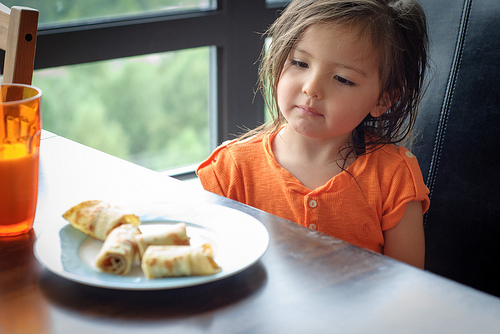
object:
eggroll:
[61, 199, 139, 241]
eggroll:
[136, 221, 189, 246]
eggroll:
[93, 223, 137, 275]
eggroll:
[140, 242, 223, 277]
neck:
[266, 128, 361, 173]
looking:
[272, 47, 378, 102]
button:
[308, 200, 319, 208]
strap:
[395, 144, 431, 199]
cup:
[0, 82, 42, 248]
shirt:
[194, 122, 430, 253]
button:
[404, 150, 414, 159]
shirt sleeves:
[371, 138, 432, 231]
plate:
[30, 196, 270, 290]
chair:
[0, 4, 39, 84]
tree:
[24, 47, 216, 172]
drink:
[0, 142, 39, 238]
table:
[0, 129, 499, 334]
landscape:
[20, 49, 223, 174]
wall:
[0, 0, 289, 177]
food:
[60, 198, 223, 278]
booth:
[362, 0, 500, 300]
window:
[0, 0, 292, 181]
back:
[0, 3, 38, 86]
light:
[261, 263, 408, 332]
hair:
[232, 0, 437, 203]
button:
[308, 224, 317, 231]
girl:
[198, 0, 429, 265]